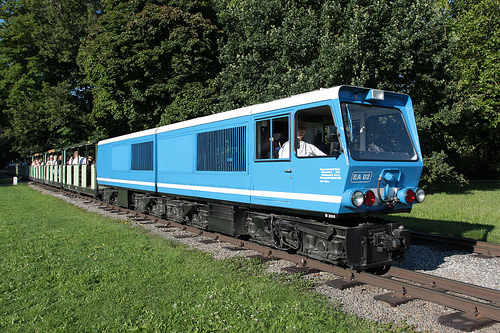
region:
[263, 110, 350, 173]
a man driving the train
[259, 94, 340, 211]
a man driving the train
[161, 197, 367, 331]
the train tracks are brown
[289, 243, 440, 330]
the train tracks are brown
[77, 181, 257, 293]
the train tracks are brown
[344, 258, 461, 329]
the train tracks are brown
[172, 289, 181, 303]
patch of green grass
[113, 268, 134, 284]
patch of green grass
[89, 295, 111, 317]
patch of green grass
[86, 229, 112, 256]
patch of green grass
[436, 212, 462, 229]
patch of green grass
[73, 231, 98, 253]
patch of green grass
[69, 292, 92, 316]
patch of green grass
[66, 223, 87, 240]
patch of green grass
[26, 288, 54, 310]
patch of green grass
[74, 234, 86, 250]
patch of green grass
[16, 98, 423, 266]
a blue train on the tracks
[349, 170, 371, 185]
white numbers and letters on the front of the train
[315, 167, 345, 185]
white lettering on the side of the train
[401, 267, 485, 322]
black metal train tracks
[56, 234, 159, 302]
green grass of the ground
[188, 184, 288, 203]
white stripe on the side of the blue train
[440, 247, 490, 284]
grey grave in between the tracks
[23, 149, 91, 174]
many people riding in the train cars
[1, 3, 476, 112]
many trees growing behind the train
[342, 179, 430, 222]
red and white headlights of the train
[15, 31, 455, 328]
The train is on the tracks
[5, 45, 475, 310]
The train is carrying passengers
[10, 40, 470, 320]
A train is in an amusement park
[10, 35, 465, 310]
The train is an amusement park ride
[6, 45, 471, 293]
The train is pulling several cars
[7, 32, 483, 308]
The train is passing some trees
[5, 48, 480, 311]
The train is loaded with people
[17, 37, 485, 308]
The train is running in daytime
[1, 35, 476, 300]
The train is owned by the park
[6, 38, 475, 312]
The train is out in the sunshine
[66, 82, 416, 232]
the train is blue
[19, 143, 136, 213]
the train cart is green